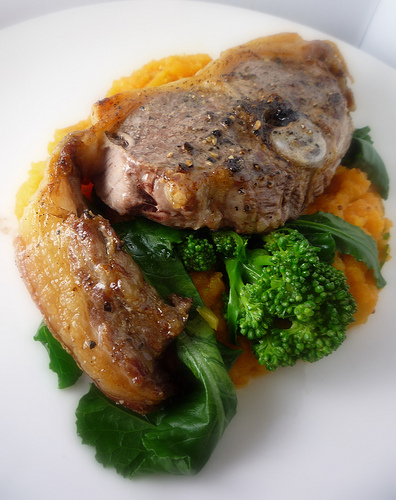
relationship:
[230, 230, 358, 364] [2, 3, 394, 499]
broccoli on plate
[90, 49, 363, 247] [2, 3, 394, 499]
meat on plate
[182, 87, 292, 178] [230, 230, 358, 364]
spices on broccoli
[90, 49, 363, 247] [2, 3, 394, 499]
steak on plate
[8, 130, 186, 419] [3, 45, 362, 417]
bacon around steak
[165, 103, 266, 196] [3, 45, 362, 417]
peppercorns on steak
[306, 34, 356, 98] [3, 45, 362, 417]
fat on edge of steak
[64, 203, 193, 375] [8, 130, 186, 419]
pepper on bacon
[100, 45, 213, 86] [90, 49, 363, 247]
sweet potato under meat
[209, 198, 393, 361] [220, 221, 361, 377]
sweet potato under broccoli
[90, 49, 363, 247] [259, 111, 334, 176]
meat with bone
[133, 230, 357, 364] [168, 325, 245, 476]
broccoli next to lettuce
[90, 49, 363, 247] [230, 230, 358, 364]
meat on top broccoli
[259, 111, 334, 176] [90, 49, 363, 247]
bones into edges of meat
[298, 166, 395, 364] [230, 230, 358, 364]
sweet potato under broccoli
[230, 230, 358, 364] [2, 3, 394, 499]
broccoli on white plate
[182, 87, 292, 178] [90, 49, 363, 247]
condiment over meat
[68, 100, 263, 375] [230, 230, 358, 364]
pepper on broccoli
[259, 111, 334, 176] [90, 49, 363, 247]
bone in meat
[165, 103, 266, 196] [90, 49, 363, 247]
seasoning on meat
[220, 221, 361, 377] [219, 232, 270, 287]
broccoli has stem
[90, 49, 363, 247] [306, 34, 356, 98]
meat has fat